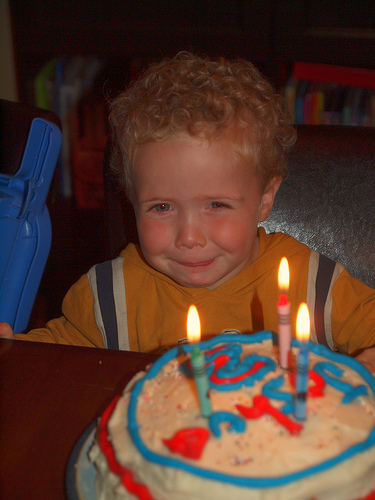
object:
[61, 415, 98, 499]
platter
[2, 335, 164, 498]
table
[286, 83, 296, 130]
books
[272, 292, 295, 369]
red crayon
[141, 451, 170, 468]
blue icing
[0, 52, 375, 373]
boy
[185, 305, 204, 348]
flames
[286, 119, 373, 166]
chair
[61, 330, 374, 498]
birthday cake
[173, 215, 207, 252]
nose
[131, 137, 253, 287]
face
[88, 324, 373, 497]
frosting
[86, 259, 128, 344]
stripe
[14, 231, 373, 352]
shirt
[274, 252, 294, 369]
candle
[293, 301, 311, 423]
candle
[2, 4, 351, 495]
party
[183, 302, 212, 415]
candle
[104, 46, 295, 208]
curly hair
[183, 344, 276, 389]
number 2